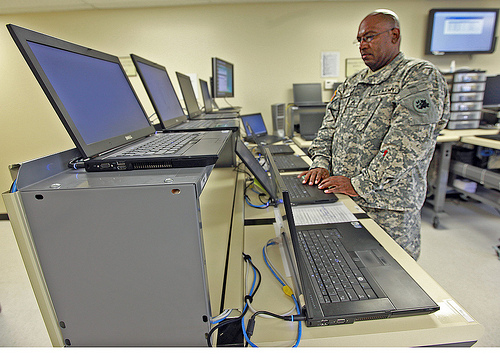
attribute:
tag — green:
[363, 83, 410, 98]